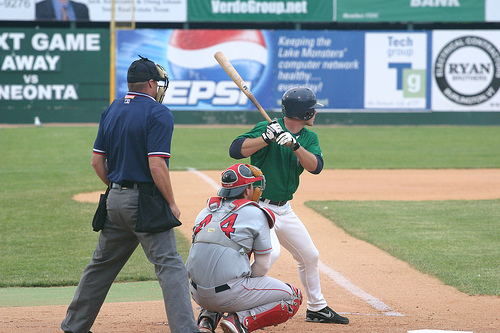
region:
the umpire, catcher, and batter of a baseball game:
[66, 46, 353, 331]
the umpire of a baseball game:
[58, 55, 190, 330]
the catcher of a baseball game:
[178, 158, 303, 332]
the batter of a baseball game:
[207, 41, 334, 170]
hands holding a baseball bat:
[215, 47, 298, 153]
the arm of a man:
[144, 118, 182, 220]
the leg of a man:
[147, 232, 194, 332]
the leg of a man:
[286, 224, 328, 307]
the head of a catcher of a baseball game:
[215, 157, 268, 206]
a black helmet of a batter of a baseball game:
[281, 83, 324, 126]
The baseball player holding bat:
[228, 86, 348, 321]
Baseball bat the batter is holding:
[215, 50, 292, 145]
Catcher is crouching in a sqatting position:
[186, 163, 303, 330]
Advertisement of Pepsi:
[115, 26, 363, 108]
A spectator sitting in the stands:
[32, 0, 89, 19]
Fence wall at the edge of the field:
[0, 22, 499, 124]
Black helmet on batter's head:
[282, 85, 322, 119]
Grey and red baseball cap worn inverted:
[216, 163, 264, 198]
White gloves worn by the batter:
[261, 120, 298, 149]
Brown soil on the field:
[0, 169, 499, 330]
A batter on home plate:
[227, 34, 350, 322]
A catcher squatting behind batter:
[187, 145, 307, 326]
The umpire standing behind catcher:
[65, 55, 187, 320]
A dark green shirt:
[247, 112, 318, 199]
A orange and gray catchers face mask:
[211, 143, 267, 208]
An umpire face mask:
[124, 48, 178, 103]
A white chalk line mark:
[188, 163, 387, 320]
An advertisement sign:
[116, 29, 430, 114]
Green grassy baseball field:
[18, 130, 69, 250]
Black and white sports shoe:
[307, 302, 350, 327]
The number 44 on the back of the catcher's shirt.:
[189, 208, 237, 238]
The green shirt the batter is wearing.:
[250, 122, 317, 200]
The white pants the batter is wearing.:
[255, 198, 332, 317]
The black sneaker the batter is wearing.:
[305, 300, 347, 322]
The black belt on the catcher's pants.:
[191, 281, 235, 298]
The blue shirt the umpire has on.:
[100, 95, 174, 192]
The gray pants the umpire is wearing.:
[68, 191, 197, 331]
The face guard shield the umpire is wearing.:
[150, 57, 173, 102]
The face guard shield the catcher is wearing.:
[248, 166, 265, 205]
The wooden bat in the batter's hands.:
[208, 55, 298, 147]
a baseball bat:
[208, 53, 264, 110]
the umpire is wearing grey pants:
[157, 255, 198, 332]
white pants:
[284, 228, 328, 286]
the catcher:
[197, 159, 277, 305]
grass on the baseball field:
[405, 198, 477, 258]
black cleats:
[307, 303, 350, 323]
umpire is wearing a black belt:
[107, 182, 125, 192]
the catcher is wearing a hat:
[216, 165, 256, 197]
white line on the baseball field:
[336, 276, 386, 314]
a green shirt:
[271, 158, 294, 194]